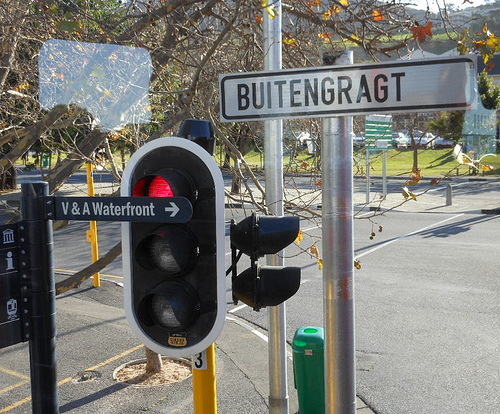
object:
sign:
[218, 56, 478, 123]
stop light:
[119, 136, 227, 359]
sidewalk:
[55, 288, 127, 413]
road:
[364, 180, 499, 350]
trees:
[395, 111, 450, 174]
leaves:
[472, 20, 499, 63]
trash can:
[292, 326, 326, 414]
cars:
[407, 132, 438, 146]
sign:
[0, 221, 21, 349]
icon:
[5, 251, 14, 271]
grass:
[388, 154, 411, 170]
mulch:
[412, 170, 420, 172]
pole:
[85, 164, 100, 288]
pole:
[320, 50, 356, 414]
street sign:
[54, 196, 193, 224]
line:
[228, 213, 301, 312]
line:
[27, 340, 56, 413]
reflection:
[38, 38, 152, 132]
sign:
[365, 114, 394, 152]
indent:
[71, 370, 103, 384]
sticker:
[193, 350, 208, 370]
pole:
[192, 342, 217, 413]